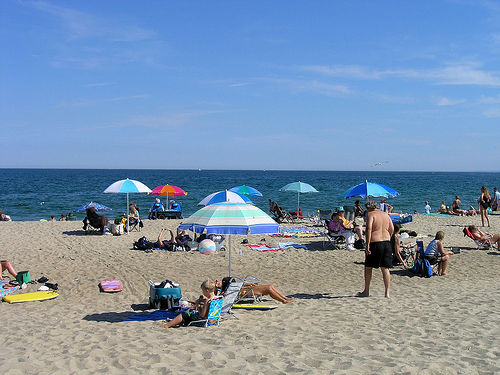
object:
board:
[2, 290, 60, 304]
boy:
[159, 280, 219, 330]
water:
[4, 166, 497, 223]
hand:
[365, 245, 371, 256]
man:
[357, 201, 394, 299]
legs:
[357, 251, 378, 297]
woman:
[427, 229, 454, 276]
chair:
[424, 240, 454, 276]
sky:
[0, 1, 497, 171]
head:
[435, 230, 445, 240]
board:
[231, 304, 278, 310]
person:
[214, 279, 296, 304]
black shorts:
[365, 241, 394, 269]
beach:
[0, 215, 500, 375]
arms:
[158, 232, 166, 248]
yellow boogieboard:
[4, 288, 56, 303]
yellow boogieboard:
[234, 299, 277, 311]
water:
[7, 165, 493, 207]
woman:
[478, 182, 493, 226]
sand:
[0, 216, 500, 375]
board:
[99, 279, 123, 292]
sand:
[0, 210, 497, 371]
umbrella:
[102, 177, 153, 236]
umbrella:
[178, 199, 278, 277]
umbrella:
[278, 180, 320, 220]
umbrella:
[338, 180, 401, 206]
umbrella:
[198, 190, 245, 206]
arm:
[366, 212, 374, 246]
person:
[133, 227, 184, 250]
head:
[365, 201, 380, 212]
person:
[424, 230, 454, 275]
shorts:
[358, 240, 394, 268]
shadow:
[282, 288, 364, 303]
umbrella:
[118, 177, 313, 264]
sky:
[22, 16, 495, 146]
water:
[15, 136, 497, 184]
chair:
[187, 295, 224, 328]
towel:
[116, 227, 216, 264]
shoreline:
[9, 214, 484, 374]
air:
[133, 228, 191, 252]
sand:
[10, 303, 66, 307]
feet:
[356, 291, 370, 297]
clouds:
[297, 61, 500, 87]